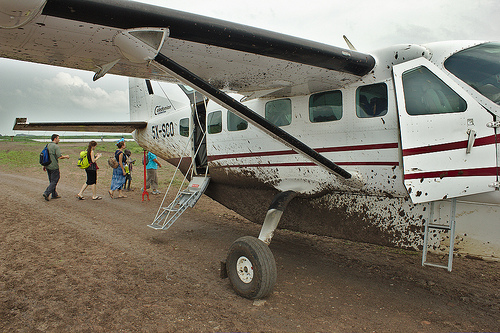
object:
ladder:
[422, 197, 457, 272]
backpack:
[40, 144, 52, 167]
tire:
[225, 236, 278, 300]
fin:
[13, 118, 145, 133]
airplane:
[0, 0, 499, 298]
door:
[390, 56, 495, 204]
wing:
[0, 10, 374, 96]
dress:
[110, 162, 127, 191]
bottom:
[204, 187, 500, 262]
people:
[39, 134, 162, 202]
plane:
[0, 0, 500, 330]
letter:
[151, 122, 174, 139]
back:
[100, 66, 256, 200]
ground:
[76, 230, 117, 280]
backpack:
[77, 150, 90, 170]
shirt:
[45, 142, 62, 170]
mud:
[179, 161, 385, 246]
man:
[39, 134, 69, 201]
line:
[166, 134, 500, 179]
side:
[174, 197, 433, 278]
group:
[40, 134, 160, 201]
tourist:
[40, 134, 160, 201]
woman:
[78, 141, 103, 200]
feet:
[76, 194, 103, 200]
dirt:
[65, 227, 115, 269]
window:
[355, 82, 388, 119]